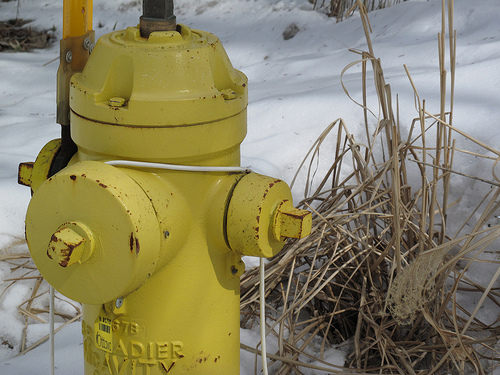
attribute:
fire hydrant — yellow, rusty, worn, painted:
[17, 23, 313, 374]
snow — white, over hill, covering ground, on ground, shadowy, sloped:
[2, 1, 500, 374]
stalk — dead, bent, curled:
[290, 117, 355, 191]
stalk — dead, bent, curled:
[341, 58, 380, 121]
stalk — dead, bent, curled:
[407, 157, 499, 188]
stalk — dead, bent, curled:
[425, 110, 500, 156]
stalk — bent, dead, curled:
[404, 63, 425, 138]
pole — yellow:
[61, 0, 92, 125]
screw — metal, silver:
[83, 36, 92, 50]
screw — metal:
[65, 50, 74, 63]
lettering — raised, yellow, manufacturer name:
[81, 319, 185, 375]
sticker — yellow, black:
[93, 320, 113, 354]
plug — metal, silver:
[139, 0, 177, 39]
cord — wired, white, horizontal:
[49, 160, 270, 375]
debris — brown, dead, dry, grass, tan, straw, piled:
[1, 18, 59, 55]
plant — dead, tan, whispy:
[387, 241, 460, 324]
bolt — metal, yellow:
[107, 96, 127, 108]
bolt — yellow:
[221, 88, 240, 100]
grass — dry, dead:
[48, 285, 57, 375]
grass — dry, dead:
[2, 275, 42, 282]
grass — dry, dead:
[1, 231, 24, 241]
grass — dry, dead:
[19, 273, 42, 353]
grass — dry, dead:
[1, 251, 31, 260]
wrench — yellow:
[49, 0, 94, 177]